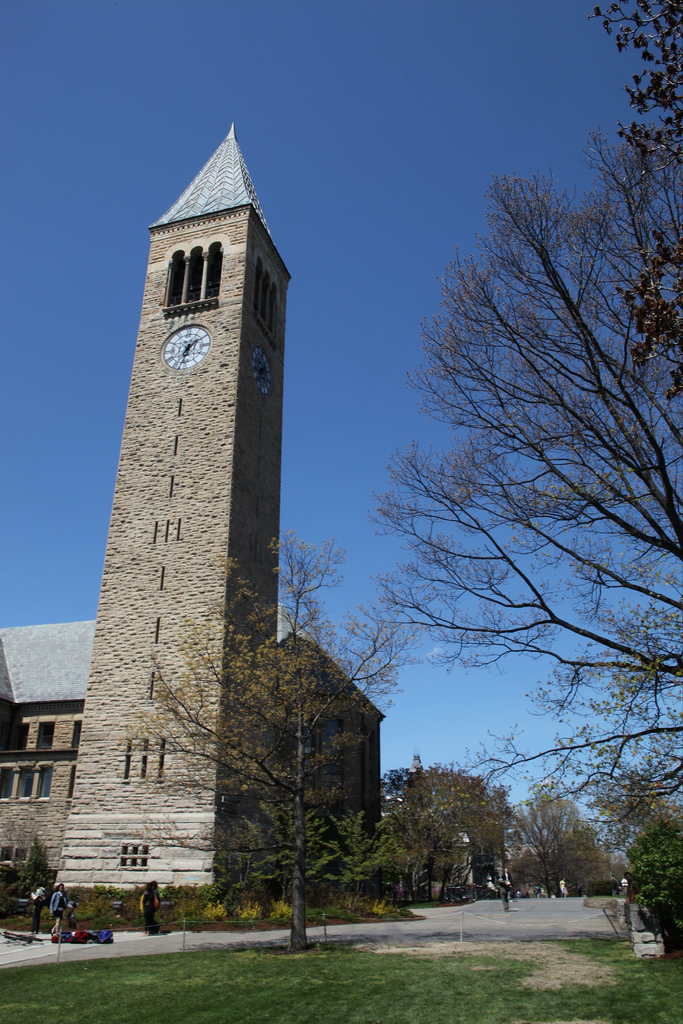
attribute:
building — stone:
[0, 605, 389, 898]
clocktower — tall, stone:
[44, 107, 303, 901]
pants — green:
[492, 880, 531, 910]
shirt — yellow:
[147, 892, 160, 908]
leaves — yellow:
[117, 531, 424, 853]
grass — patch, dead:
[371, 933, 623, 995]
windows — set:
[8, 717, 62, 817]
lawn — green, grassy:
[296, 942, 443, 1017]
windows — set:
[158, 238, 227, 325]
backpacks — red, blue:
[26, 928, 121, 952]